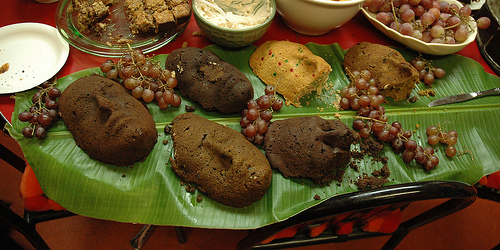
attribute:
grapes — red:
[364, 1, 494, 44]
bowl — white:
[359, 2, 486, 62]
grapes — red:
[351, 111, 440, 176]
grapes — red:
[424, 121, 465, 162]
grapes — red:
[409, 52, 449, 90]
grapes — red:
[334, 62, 391, 121]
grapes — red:
[231, 80, 287, 147]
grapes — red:
[96, 38, 185, 112]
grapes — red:
[13, 79, 68, 141]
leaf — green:
[6, 38, 500, 235]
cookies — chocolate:
[262, 111, 361, 188]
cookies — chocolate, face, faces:
[164, 45, 266, 114]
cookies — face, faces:
[260, 114, 358, 192]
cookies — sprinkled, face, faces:
[247, 32, 337, 110]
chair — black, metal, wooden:
[243, 167, 477, 250]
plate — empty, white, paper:
[1, 15, 75, 104]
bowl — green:
[188, 0, 286, 52]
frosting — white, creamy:
[195, 1, 273, 31]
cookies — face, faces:
[55, 68, 161, 173]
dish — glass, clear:
[51, 1, 193, 63]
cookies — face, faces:
[162, 107, 281, 210]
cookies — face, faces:
[338, 34, 424, 107]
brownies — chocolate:
[73, 2, 189, 38]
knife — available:
[424, 81, 500, 110]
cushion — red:
[259, 205, 406, 238]